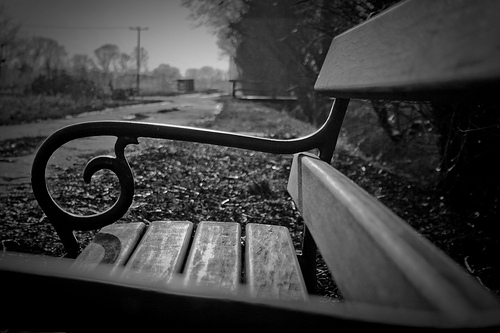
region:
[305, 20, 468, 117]
Long wooden plank on a bench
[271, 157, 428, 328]
Long wooden plank on a bench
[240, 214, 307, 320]
Long wooden plank on a bench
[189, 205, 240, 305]
Long wooden plank on a bench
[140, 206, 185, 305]
Long wooden plank on a bench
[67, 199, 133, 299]
Long wooden plank on a bench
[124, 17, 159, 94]
Large wooden electrical post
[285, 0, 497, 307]
two wood boards of bench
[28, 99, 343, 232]
curled metal arm of bench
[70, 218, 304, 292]
four boards of bench seat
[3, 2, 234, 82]
light in daytime sky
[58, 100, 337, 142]
light reflection on top of arm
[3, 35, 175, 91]
trees with no leaves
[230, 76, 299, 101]
bridge with railing on side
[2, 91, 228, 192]
surface of paved street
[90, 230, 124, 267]
shadow of curled metal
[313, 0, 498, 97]
slat on the top of a bench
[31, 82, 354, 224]
metal arm of a bench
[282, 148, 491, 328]
lower slat on the back of a bench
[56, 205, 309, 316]
wood slats on the seat of a bench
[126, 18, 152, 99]
tall electrical post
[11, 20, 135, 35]
wire running to the post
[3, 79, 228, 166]
pathway near the bench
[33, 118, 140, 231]
design on the arm of the bench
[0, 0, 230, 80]
sky in the distance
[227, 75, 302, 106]
bridge near the path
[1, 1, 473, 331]
a black and white image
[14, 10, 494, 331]
a wooden bench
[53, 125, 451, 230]
some leaves on the ground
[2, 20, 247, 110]
a row of trees in the background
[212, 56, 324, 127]
a wooden bridge in the background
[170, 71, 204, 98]
an object in the background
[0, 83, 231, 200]
a path in the area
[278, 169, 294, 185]
a piece of the image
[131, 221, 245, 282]
the seat of the bench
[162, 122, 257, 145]
the armrest of the bench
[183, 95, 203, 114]
the sidewalk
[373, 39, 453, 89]
the back of the bench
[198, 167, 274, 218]
dirt on the ground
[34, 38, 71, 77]
tall trees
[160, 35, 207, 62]
the sky is cloudy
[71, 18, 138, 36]
electrical lines in the sky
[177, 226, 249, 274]
a wooden bench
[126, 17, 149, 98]
a wood electrical pole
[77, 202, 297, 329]
a wood bench seat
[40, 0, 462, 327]
a iron and wood bench